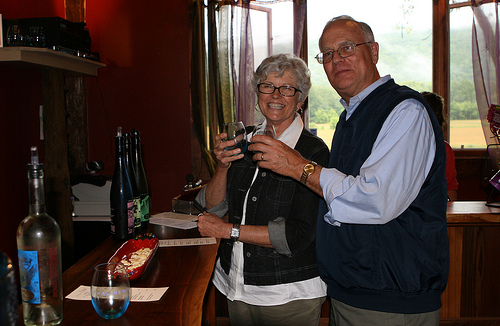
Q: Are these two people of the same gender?
A: No, they are both male and female.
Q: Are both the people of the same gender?
A: No, they are both male and female.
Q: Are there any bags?
A: No, there are no bags.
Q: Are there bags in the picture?
A: No, there are no bags.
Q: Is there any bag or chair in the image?
A: No, there are no bags or chairs.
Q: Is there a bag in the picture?
A: No, there are no bags.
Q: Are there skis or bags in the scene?
A: No, there are no bags or skis.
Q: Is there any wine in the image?
A: Yes, there is wine.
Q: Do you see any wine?
A: Yes, there is wine.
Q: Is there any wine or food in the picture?
A: Yes, there is wine.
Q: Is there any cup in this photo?
A: No, there are no cups.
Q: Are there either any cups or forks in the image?
A: No, there are no cups or forks.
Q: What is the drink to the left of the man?
A: The drink is wine.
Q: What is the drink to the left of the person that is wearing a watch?
A: The drink is wine.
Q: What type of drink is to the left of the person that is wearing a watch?
A: The drink is wine.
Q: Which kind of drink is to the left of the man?
A: The drink is wine.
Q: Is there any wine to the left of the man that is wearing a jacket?
A: Yes, there is wine to the left of the man.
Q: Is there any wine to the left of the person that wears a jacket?
A: Yes, there is wine to the left of the man.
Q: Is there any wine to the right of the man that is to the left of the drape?
A: No, the wine is to the left of the man.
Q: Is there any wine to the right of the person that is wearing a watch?
A: No, the wine is to the left of the man.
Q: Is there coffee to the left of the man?
A: No, there is wine to the left of the man.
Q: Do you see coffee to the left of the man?
A: No, there is wine to the left of the man.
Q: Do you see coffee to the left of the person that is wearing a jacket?
A: No, there is wine to the left of the man.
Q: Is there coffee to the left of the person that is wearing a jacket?
A: No, there is wine to the left of the man.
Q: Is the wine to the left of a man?
A: Yes, the wine is to the left of a man.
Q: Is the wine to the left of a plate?
A: No, the wine is to the left of a man.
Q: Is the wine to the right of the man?
A: No, the wine is to the left of the man.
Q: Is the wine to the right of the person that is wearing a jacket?
A: No, the wine is to the left of the man.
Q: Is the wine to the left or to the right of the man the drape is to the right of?
A: The wine is to the left of the man.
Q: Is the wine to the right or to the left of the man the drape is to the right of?
A: The wine is to the left of the man.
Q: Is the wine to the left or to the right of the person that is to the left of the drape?
A: The wine is to the left of the man.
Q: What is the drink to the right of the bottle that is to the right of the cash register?
A: The drink is wine.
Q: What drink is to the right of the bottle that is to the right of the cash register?
A: The drink is wine.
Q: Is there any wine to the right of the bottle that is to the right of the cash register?
A: Yes, there is wine to the right of the bottle.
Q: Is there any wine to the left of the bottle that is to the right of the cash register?
A: No, the wine is to the right of the bottle.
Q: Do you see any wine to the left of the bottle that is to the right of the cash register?
A: No, the wine is to the right of the bottle.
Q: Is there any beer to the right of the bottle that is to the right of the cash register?
A: No, there is wine to the right of the bottle.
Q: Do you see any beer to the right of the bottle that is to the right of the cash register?
A: No, there is wine to the right of the bottle.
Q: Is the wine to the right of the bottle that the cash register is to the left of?
A: Yes, the wine is to the right of the bottle.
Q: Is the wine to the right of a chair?
A: No, the wine is to the right of the bottle.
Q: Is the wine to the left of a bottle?
A: No, the wine is to the right of a bottle.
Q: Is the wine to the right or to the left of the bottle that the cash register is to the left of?
A: The wine is to the right of the bottle.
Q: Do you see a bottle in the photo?
A: Yes, there is a bottle.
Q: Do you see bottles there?
A: Yes, there is a bottle.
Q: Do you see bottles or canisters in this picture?
A: Yes, there is a bottle.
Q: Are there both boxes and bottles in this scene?
A: No, there is a bottle but no boxes.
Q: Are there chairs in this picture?
A: No, there are no chairs.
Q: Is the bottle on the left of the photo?
A: Yes, the bottle is on the left of the image.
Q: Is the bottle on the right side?
A: No, the bottle is on the left of the image.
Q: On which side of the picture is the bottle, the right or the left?
A: The bottle is on the left of the image.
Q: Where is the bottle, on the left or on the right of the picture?
A: The bottle is on the left of the image.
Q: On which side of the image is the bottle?
A: The bottle is on the left of the image.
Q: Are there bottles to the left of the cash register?
A: Yes, there is a bottle to the left of the cash register.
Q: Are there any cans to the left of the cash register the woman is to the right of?
A: No, there is a bottle to the left of the cash register.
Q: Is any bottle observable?
A: Yes, there is a bottle.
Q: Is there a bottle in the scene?
A: Yes, there is a bottle.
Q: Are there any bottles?
A: Yes, there is a bottle.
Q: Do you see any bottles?
A: Yes, there is a bottle.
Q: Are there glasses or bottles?
A: Yes, there is a bottle.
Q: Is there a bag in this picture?
A: No, there are no bags.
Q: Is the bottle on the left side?
A: Yes, the bottle is on the left of the image.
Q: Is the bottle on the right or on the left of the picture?
A: The bottle is on the left of the image.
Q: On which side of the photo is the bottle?
A: The bottle is on the left of the image.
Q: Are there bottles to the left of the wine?
A: Yes, there is a bottle to the left of the wine.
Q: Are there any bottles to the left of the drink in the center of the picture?
A: Yes, there is a bottle to the left of the wine.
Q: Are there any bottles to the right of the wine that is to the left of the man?
A: No, the bottle is to the left of the wine.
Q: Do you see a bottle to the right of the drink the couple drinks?
A: No, the bottle is to the left of the wine.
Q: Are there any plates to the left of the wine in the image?
A: No, there is a bottle to the left of the wine.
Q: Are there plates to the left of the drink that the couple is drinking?
A: No, there is a bottle to the left of the wine.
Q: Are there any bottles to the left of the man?
A: Yes, there is a bottle to the left of the man.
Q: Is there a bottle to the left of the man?
A: Yes, there is a bottle to the left of the man.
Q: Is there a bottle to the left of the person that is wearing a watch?
A: Yes, there is a bottle to the left of the man.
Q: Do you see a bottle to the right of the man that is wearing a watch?
A: No, the bottle is to the left of the man.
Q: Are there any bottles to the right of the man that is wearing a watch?
A: No, the bottle is to the left of the man.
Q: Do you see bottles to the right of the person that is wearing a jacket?
A: No, the bottle is to the left of the man.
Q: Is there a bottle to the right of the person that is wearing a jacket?
A: No, the bottle is to the left of the man.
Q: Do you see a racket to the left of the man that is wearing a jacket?
A: No, there is a bottle to the left of the man.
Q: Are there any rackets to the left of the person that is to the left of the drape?
A: No, there is a bottle to the left of the man.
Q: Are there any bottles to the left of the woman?
A: Yes, there is a bottle to the left of the woman.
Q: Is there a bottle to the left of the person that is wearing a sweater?
A: Yes, there is a bottle to the left of the woman.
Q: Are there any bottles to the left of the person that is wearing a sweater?
A: Yes, there is a bottle to the left of the woman.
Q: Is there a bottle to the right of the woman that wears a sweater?
A: No, the bottle is to the left of the woman.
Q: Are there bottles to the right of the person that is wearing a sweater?
A: No, the bottle is to the left of the woman.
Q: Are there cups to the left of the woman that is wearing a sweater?
A: No, there is a bottle to the left of the woman.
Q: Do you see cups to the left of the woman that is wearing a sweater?
A: No, there is a bottle to the left of the woman.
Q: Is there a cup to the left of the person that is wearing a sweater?
A: No, there is a bottle to the left of the woman.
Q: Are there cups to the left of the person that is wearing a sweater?
A: No, there is a bottle to the left of the woman.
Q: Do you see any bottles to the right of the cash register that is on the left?
A: Yes, there is a bottle to the right of the cash register.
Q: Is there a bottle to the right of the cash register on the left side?
A: Yes, there is a bottle to the right of the cash register.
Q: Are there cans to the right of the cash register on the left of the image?
A: No, there is a bottle to the right of the cash register.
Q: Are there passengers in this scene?
A: No, there are no passengers.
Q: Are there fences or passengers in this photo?
A: No, there are no passengers or fences.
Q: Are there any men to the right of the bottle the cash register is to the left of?
A: Yes, there is a man to the right of the bottle.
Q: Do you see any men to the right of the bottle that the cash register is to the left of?
A: Yes, there is a man to the right of the bottle.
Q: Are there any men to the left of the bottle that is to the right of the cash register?
A: No, the man is to the right of the bottle.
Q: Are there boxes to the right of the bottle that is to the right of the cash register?
A: No, there is a man to the right of the bottle.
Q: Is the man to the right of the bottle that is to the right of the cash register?
A: Yes, the man is to the right of the bottle.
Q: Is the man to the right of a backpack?
A: No, the man is to the right of the bottle.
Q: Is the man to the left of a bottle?
A: No, the man is to the right of a bottle.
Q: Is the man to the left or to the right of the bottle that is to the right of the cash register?
A: The man is to the right of the bottle.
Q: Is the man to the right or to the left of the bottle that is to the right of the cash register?
A: The man is to the right of the bottle.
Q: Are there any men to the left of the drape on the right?
A: Yes, there is a man to the left of the drape.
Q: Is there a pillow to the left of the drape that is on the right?
A: No, there is a man to the left of the drapery.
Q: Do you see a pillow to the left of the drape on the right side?
A: No, there is a man to the left of the drapery.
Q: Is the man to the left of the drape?
A: Yes, the man is to the left of the drape.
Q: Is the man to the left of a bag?
A: No, the man is to the left of the drape.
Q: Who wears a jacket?
A: The man wears a jacket.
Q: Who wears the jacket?
A: The man wears a jacket.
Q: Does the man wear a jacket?
A: Yes, the man wears a jacket.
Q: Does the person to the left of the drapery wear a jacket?
A: Yes, the man wears a jacket.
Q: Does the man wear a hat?
A: No, the man wears a jacket.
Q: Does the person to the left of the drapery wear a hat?
A: No, the man wears a jacket.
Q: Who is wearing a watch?
A: The man is wearing a watch.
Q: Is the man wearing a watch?
A: Yes, the man is wearing a watch.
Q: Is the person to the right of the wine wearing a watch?
A: Yes, the man is wearing a watch.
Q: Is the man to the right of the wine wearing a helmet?
A: No, the man is wearing a watch.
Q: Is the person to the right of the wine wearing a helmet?
A: No, the man is wearing a watch.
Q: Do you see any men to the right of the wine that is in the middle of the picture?
A: Yes, there is a man to the right of the wine.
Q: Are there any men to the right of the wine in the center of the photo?
A: Yes, there is a man to the right of the wine.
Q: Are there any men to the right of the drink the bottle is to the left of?
A: Yes, there is a man to the right of the wine.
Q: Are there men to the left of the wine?
A: No, the man is to the right of the wine.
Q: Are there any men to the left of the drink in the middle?
A: No, the man is to the right of the wine.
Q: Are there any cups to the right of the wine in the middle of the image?
A: No, there is a man to the right of the wine.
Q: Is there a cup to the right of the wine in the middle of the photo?
A: No, there is a man to the right of the wine.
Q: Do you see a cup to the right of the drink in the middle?
A: No, there is a man to the right of the wine.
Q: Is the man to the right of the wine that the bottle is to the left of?
A: Yes, the man is to the right of the wine.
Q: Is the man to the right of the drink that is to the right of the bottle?
A: Yes, the man is to the right of the wine.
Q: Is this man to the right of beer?
A: No, the man is to the right of the wine.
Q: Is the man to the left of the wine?
A: No, the man is to the right of the wine.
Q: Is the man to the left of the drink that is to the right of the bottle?
A: No, the man is to the right of the wine.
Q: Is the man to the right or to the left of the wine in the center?
A: The man is to the right of the wine.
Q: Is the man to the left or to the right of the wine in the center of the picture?
A: The man is to the right of the wine.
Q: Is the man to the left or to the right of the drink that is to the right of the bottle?
A: The man is to the right of the wine.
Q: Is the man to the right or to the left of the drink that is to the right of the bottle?
A: The man is to the right of the wine.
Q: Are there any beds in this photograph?
A: No, there are no beds.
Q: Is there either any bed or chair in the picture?
A: No, there are no beds or chairs.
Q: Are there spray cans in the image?
A: No, there are no spray cans.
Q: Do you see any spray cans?
A: No, there are no spray cans.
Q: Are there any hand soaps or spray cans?
A: No, there are no spray cans or hand soaps.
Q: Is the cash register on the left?
A: Yes, the cash register is on the left of the image.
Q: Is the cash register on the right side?
A: No, the cash register is on the left of the image.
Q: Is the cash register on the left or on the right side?
A: The cash register is on the left of the image.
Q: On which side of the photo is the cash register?
A: The cash register is on the left of the image.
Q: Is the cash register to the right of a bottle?
A: Yes, the cash register is to the right of a bottle.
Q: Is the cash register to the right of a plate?
A: No, the cash register is to the right of a bottle.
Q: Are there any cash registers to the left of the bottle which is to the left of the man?
A: Yes, there is a cash register to the left of the bottle.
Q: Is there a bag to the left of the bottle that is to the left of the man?
A: No, there is a cash register to the left of the bottle.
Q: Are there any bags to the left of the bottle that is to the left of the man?
A: No, there is a cash register to the left of the bottle.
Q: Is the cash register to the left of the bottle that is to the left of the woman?
A: Yes, the cash register is to the left of the bottle.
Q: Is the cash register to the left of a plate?
A: No, the cash register is to the left of the bottle.